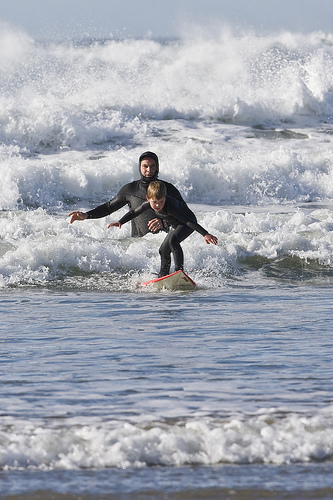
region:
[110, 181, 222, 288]
Boy on a surfboard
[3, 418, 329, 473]
Foamy white water in ocean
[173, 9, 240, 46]
White spray of water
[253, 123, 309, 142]
Water between white splashes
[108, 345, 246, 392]
Ripples in the water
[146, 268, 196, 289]
Red and white surfboard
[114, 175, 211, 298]
the boy is surfing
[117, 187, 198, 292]
the boy is surfing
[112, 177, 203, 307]
the boy is surfing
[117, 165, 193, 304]
the boy is surfing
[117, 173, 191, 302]
the boy is surfing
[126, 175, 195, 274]
boy on the surfboard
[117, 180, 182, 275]
boy on the surfboard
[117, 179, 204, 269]
boy on the surfboard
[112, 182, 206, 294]
boy on the surfboard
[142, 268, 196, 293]
a white and red surfboard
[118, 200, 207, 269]
a childs black wet suit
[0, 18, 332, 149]
waves breaking behind the surfer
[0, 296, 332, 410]
calm water between the waves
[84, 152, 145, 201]
the mans full wetsuit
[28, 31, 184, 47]
blue ocean behind the waves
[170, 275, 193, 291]
branding and art design on the surfboard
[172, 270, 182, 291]
the surfboards stringer is red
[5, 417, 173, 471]
The white foam from the waves.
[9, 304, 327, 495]
The large body of water.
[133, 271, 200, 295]
The young boy is on a red and white surfboard.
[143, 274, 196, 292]
The bottom of the surfboard is white.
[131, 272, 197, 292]
The top of the surfboard is red.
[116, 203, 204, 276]
The boy is in a wet suit.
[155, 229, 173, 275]
the left leg of the boy.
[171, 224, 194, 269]
The right leg of the boy.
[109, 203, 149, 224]
The left hand of the boy.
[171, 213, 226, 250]
The right hand of the boy.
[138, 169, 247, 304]
a boy wearing a wetsuit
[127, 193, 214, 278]
a boy wearing a black wetsuit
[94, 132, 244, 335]
a man wearing a wetsuit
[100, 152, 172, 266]
a man wearing black wetsuit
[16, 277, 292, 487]
a body of water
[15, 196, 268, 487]
a body of water with waves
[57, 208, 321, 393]
a body of wavy water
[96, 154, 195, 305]
two people in the water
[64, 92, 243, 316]
an adult and child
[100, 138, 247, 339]
two people wearing wetsuit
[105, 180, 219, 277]
A boy is learning how to surf.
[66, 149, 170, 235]
A man is teaching a boy how to surf.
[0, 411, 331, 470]
The crest of a wave heading to shore.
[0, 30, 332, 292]
A huge wave is crashing down around the two surfers.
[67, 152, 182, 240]
Man in a wetsuit helping the boy surf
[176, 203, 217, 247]
Boy's extended left arm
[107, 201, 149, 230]
Boy's extended right arm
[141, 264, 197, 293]
Red and white surfboard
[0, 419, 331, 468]
Foam from the waves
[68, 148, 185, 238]
Wetsuit on the man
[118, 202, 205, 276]
Black wetsuit on the boy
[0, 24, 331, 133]
Crashing waves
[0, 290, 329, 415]
Calm water between the waves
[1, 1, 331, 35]
blue of daytime sky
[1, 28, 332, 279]
white water of crashed waves